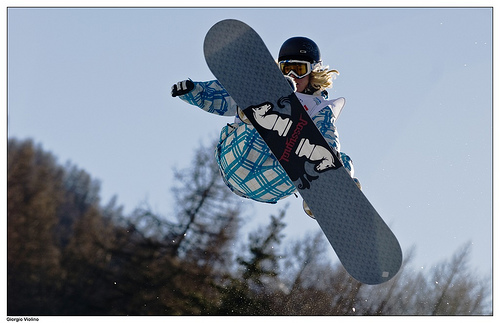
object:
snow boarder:
[170, 33, 365, 217]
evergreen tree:
[0, 141, 54, 313]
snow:
[207, 272, 295, 295]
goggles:
[278, 58, 317, 79]